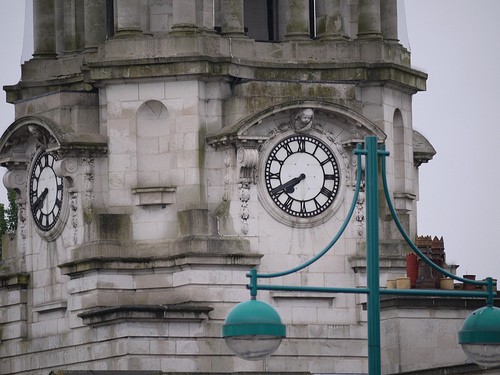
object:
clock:
[259, 135, 344, 219]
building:
[1, 0, 498, 374]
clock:
[29, 151, 66, 238]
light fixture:
[221, 134, 499, 374]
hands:
[271, 173, 304, 196]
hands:
[30, 188, 48, 210]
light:
[224, 298, 285, 363]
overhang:
[411, 129, 435, 164]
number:
[296, 139, 306, 153]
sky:
[406, 3, 496, 280]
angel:
[292, 107, 314, 136]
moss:
[287, 15, 311, 37]